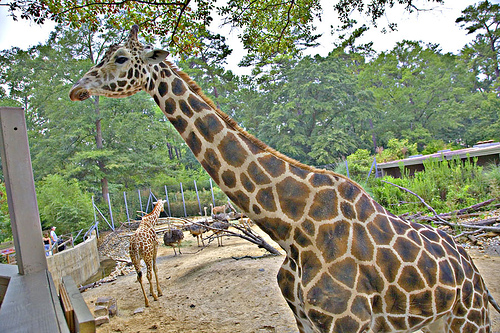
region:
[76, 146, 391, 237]
Metal fence and posts around enclosure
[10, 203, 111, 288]
Tan stone wall around enclosure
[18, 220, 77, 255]
People looking in enclosure at animals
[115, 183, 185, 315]
Smaller lighter giraffe in distance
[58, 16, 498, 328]
Tall giraffe in forefront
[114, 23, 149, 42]
Horn on giraffe's head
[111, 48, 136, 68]
Giraffe's pretty eye that is large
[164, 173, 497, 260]
Wooden sticks and twigs in the enclosure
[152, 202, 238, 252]
Three ostriches in enclosure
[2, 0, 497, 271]
Area of tall trees outside of enclosure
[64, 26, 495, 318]
Animals in the zoo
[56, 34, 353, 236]
giraffe with a long neck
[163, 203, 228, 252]
ostrich in the zoo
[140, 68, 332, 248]
Giraffe with a long neck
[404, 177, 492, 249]
branches on the ground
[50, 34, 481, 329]
Animals in the zoo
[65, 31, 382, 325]
Animals in the zoo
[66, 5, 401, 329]
Animals in the zoo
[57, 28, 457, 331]
Animals in the zoo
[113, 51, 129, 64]
the eye of a giraffe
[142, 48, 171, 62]
the ear of a giraffe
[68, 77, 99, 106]
the mouth of a giraffe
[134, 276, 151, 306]
the leg of a giraffe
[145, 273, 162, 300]
the leg of a giraffe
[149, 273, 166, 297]
the leg of a giraffe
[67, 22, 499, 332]
a giraffe behind a fence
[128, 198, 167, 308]
a giraffe behind a fence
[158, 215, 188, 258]
a ostrich behind a fence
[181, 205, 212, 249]
a ostrich behind a fence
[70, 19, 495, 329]
Giraffe in the forefront.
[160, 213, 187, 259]
Ostrich in the background.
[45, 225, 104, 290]
Brick wall in the background.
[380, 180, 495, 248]
Branches in the background.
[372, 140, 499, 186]
structure in the background.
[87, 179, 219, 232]
Metal poles in the background.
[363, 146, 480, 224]
Over grown weeds in the background.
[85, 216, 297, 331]
Dirt covering the ground.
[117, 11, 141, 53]
Horns on the giraffe.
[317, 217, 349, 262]
Black and brown spot on the giraffe.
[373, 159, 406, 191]
part of a house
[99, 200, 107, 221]
part of a wall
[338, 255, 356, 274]
part of a rock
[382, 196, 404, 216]
part of a bush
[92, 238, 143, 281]
part of a tail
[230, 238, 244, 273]
edge of a root